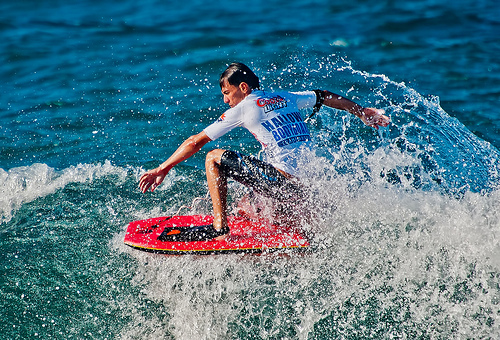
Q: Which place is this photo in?
A: It is at the sea.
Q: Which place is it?
A: It is a sea.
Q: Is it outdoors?
A: Yes, it is outdoors.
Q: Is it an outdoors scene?
A: Yes, it is outdoors.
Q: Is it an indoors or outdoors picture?
A: It is outdoors.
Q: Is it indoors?
A: No, it is outdoors.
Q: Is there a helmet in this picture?
A: No, there are no helmets.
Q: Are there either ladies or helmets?
A: No, there are no helmets or ladies.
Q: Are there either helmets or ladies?
A: No, there are no helmets or ladies.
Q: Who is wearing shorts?
A: The man is wearing shorts.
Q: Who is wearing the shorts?
A: The man is wearing shorts.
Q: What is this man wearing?
A: The man is wearing shorts.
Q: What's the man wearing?
A: The man is wearing shorts.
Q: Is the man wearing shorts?
A: Yes, the man is wearing shorts.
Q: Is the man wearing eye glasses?
A: No, the man is wearing shorts.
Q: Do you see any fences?
A: No, there are no fences.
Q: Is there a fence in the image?
A: No, there are no fences.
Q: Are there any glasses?
A: No, there are no glasses.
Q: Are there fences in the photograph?
A: No, there are no fences.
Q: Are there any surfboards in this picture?
A: Yes, there is a surfboard.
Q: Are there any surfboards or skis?
A: Yes, there is a surfboard.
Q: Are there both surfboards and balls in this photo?
A: No, there is a surfboard but no balls.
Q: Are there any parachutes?
A: No, there are no parachutes.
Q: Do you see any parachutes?
A: No, there are no parachutes.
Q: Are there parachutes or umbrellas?
A: No, there are no parachutes or umbrellas.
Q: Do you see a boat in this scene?
A: No, there are no boats.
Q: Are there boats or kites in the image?
A: No, there are no boats or kites.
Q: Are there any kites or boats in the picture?
A: No, there are no boats or kites.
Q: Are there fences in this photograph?
A: No, there are no fences.